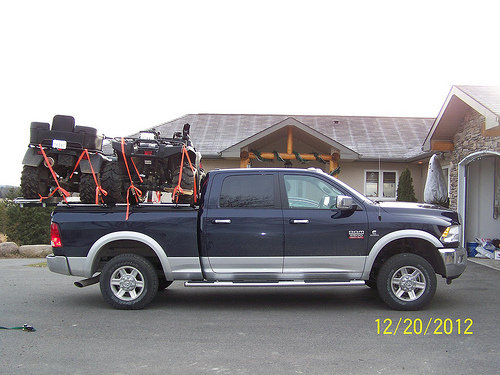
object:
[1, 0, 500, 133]
clouds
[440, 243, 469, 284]
bumper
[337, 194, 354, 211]
mirror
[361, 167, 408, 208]
windows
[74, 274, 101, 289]
exhaust pipe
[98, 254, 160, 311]
tires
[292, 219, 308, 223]
handle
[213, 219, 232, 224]
handle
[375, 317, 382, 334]
numbers one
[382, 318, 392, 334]
numbers two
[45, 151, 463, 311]
truck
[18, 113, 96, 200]
wheelers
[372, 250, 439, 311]
wheel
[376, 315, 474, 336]
date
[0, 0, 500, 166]
sky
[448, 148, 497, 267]
garage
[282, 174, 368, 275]
door panel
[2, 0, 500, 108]
white clouds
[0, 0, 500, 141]
white clouds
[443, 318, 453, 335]
zero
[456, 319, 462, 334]
one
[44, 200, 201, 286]
truck bed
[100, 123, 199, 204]
atvs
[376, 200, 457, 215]
hood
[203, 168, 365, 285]
cab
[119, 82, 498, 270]
building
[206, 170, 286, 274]
door panel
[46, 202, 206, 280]
bed